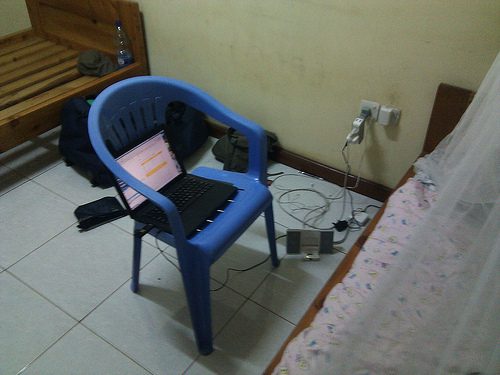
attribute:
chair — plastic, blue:
[88, 76, 283, 353]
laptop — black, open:
[107, 123, 234, 236]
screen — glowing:
[114, 133, 180, 208]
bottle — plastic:
[113, 21, 135, 66]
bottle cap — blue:
[116, 19, 122, 26]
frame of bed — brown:
[266, 84, 473, 374]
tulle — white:
[272, 52, 499, 372]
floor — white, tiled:
[1, 127, 388, 373]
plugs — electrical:
[339, 106, 369, 192]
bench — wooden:
[0, 30, 141, 153]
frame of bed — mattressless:
[1, 1, 149, 150]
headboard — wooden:
[423, 84, 472, 161]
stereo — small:
[287, 231, 332, 260]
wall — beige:
[138, 4, 500, 186]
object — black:
[72, 197, 129, 229]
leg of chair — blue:
[177, 250, 217, 355]